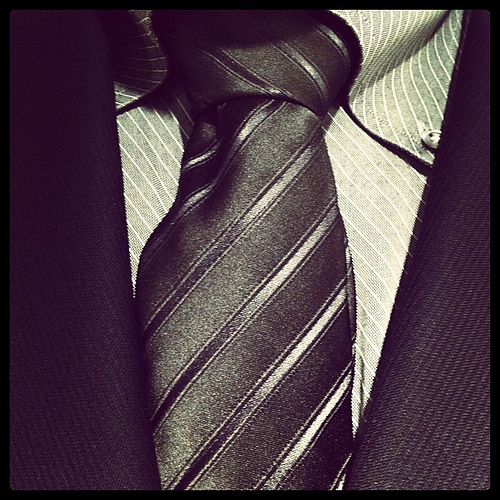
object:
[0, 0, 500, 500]
suit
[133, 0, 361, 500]
tie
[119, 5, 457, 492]
shirt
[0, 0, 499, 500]
jacket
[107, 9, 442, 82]
neck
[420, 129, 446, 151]
button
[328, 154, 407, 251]
stripes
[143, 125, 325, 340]
lines